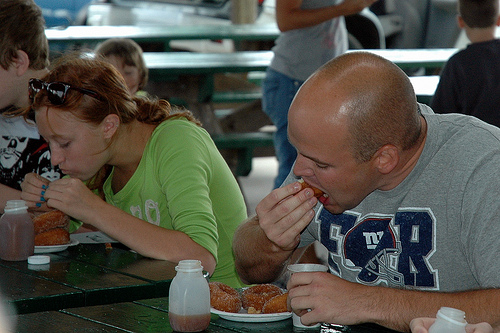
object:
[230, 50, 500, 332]
man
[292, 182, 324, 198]
doughnut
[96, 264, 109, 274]
table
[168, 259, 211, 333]
jug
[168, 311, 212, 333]
juice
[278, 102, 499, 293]
tee shirt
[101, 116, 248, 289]
shirt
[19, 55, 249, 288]
woman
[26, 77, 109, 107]
sunglasses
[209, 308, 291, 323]
plate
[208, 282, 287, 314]
donuts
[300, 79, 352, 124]
bald head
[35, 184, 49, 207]
finger nails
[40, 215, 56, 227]
sugar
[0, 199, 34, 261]
bottle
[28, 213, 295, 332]
food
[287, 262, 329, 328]
cup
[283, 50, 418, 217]
head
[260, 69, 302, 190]
jeans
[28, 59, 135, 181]
head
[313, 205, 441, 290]
logo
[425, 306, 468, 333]
container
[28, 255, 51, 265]
cap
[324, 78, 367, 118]
shine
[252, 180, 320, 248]
hand